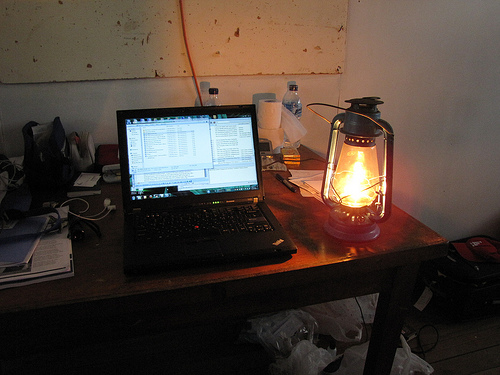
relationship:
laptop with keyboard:
[112, 102, 299, 274] [131, 200, 278, 246]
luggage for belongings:
[415, 231, 499, 323] [406, 231, 499, 330]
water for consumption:
[282, 83, 303, 152] [280, 84, 304, 151]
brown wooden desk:
[325, 244, 363, 263] [2, 122, 448, 374]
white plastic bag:
[329, 308, 354, 327] [307, 303, 366, 348]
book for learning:
[0, 202, 81, 288] [1, 204, 85, 293]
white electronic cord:
[104, 200, 109, 204] [50, 192, 122, 227]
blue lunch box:
[57, 125, 65, 142] [18, 114, 78, 196]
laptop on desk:
[112, 102, 299, 274] [2, 122, 448, 374]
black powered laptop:
[233, 237, 267, 250] [112, 102, 299, 274]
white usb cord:
[329, 308, 354, 327] [50, 192, 122, 227]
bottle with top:
[280, 83, 304, 150] [288, 84, 300, 92]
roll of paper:
[255, 95, 284, 130] [253, 95, 307, 152]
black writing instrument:
[233, 237, 267, 250] [113, 102, 300, 279]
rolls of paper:
[254, 97, 309, 161] [253, 95, 307, 152]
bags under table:
[238, 277, 445, 374] [1, 120, 450, 374]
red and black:
[458, 243, 475, 261] [466, 272, 484, 285]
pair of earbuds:
[57, 193, 122, 226] [54, 194, 120, 223]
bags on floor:
[238, 277, 445, 374] [215, 236, 500, 374]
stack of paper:
[1, 203, 77, 289] [0, 199, 82, 293]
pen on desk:
[271, 168, 300, 195] [2, 122, 448, 374]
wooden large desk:
[0, 133, 454, 277] [2, 122, 448, 374]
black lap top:
[233, 237, 267, 250] [112, 103, 271, 211]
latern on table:
[306, 88, 401, 245] [1, 120, 450, 374]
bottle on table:
[280, 83, 304, 150] [1, 120, 450, 374]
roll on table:
[255, 95, 284, 130] [1, 120, 450, 374]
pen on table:
[271, 168, 300, 195] [1, 120, 450, 374]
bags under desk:
[238, 277, 445, 374] [2, 122, 448, 374]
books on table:
[0, 202, 81, 288] [1, 120, 450, 374]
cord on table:
[50, 192, 122, 227] [1, 120, 450, 374]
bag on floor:
[412, 230, 498, 315] [215, 236, 500, 374]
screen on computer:
[122, 115, 266, 201] [113, 101, 302, 287]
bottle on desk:
[280, 83, 304, 150] [2, 122, 448, 374]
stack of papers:
[1, 203, 77, 289] [0, 199, 82, 293]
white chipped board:
[13, 13, 208, 48] [0, 0, 354, 85]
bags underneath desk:
[238, 277, 445, 374] [2, 122, 448, 374]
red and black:
[458, 243, 475, 261] [233, 237, 267, 250]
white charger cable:
[104, 200, 109, 204] [56, 194, 119, 224]